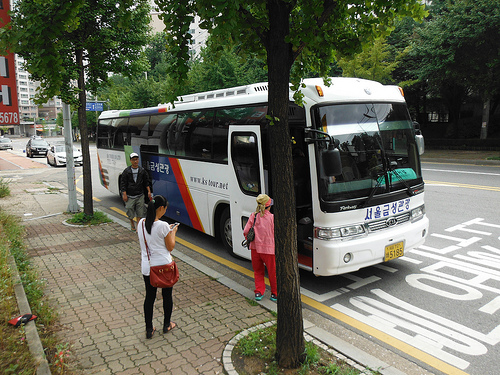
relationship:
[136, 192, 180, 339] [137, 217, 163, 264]
person has back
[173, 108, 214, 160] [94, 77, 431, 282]
window on bus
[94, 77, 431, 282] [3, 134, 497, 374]
bus on street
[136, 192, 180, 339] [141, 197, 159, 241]
person with hair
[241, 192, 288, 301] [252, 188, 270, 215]
person with blonde hair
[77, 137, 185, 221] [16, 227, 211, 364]
man walking on sidewalk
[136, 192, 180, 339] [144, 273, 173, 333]
person wearing woman's leggings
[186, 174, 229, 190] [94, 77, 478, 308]
text on bus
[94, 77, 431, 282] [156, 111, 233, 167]
bus has window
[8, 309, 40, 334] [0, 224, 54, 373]
book sitting on step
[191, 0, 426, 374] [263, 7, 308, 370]
tree has trunk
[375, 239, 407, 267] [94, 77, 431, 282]
license plate on bus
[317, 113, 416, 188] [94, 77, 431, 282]
front windshield on bus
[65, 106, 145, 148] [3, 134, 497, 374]
sign on street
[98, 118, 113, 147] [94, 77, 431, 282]
window on bus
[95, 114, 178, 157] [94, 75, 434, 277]
window on bus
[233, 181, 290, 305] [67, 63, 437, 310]
person boarding bus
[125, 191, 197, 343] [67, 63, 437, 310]
person boarding bus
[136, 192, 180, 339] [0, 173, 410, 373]
person standing on sidewalk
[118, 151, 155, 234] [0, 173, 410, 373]
man standing on sidewalk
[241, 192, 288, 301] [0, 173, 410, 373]
person standing on sidewalk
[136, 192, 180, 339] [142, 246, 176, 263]
person has waist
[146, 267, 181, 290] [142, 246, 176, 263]
bag on waist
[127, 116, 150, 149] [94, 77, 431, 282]
window on bus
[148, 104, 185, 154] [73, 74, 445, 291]
glass window on bus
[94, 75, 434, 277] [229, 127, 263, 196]
bus has window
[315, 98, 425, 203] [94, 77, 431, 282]
front windshield on bus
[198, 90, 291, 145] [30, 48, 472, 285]
glass on bus